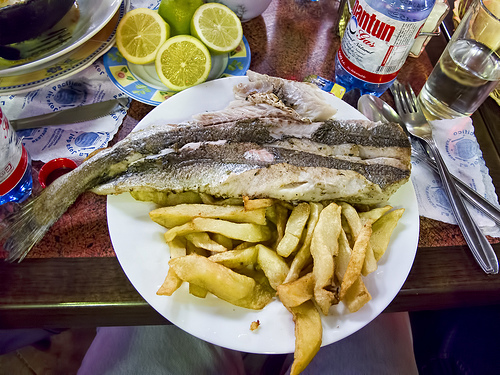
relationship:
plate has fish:
[202, 86, 224, 106] [156, 107, 376, 182]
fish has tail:
[156, 107, 376, 182] [0, 193, 64, 267]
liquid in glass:
[449, 54, 491, 83] [438, 4, 499, 99]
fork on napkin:
[396, 88, 459, 160] [435, 118, 485, 177]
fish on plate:
[156, 107, 376, 182] [202, 86, 224, 106]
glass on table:
[438, 4, 499, 99] [37, 242, 113, 307]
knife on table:
[36, 83, 129, 130] [37, 242, 113, 307]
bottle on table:
[335, 8, 424, 75] [37, 242, 113, 307]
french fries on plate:
[209, 210, 345, 286] [202, 86, 224, 106]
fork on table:
[396, 88, 459, 160] [37, 242, 113, 307]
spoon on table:
[352, 89, 415, 139] [37, 242, 113, 307]